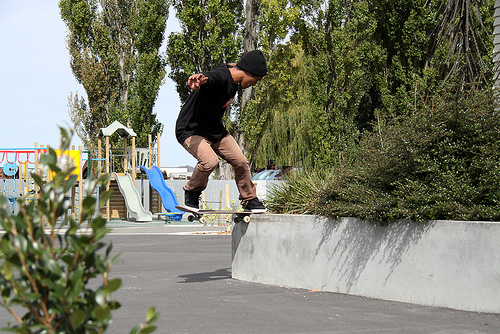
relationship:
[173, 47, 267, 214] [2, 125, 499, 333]
man performs in park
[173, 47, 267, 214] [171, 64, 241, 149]
man wearing shirt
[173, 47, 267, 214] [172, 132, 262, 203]
man wearing pants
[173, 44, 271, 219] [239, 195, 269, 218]
man wearing shoe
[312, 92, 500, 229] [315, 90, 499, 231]
bush has leaves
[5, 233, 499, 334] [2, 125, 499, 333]
sidewalk in park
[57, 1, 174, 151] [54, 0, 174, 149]
tree has leaves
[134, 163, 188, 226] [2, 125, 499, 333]
slide in park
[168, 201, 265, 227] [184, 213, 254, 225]
skateboard has wheels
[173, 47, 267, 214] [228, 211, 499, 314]
man on wall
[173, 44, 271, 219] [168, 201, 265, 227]
man on skateboard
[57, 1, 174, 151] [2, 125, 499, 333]
tree in park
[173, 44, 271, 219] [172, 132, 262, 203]
man wearing pants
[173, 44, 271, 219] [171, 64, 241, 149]
man wearing shirt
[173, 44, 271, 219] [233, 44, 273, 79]
man wearing cap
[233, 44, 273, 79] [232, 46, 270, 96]
cap on head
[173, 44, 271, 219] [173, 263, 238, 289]
man has shadow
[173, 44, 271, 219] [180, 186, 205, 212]
man wearing shoe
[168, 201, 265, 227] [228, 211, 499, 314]
skateboard on wall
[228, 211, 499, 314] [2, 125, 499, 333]
wall in park